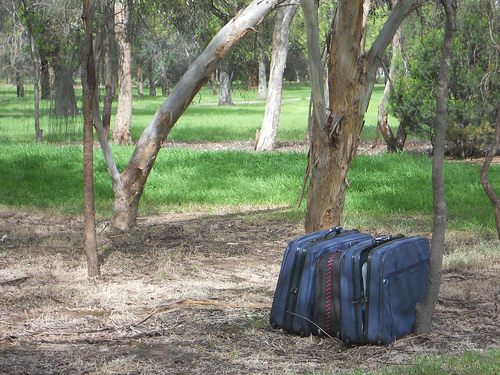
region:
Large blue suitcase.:
[341, 236, 430, 345]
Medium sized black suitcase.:
[307, 247, 348, 334]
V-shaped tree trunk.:
[379, 69, 406, 150]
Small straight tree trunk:
[80, 1, 95, 278]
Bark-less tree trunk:
[301, 0, 366, 230]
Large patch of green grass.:
[1, 155, 496, 205]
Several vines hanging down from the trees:
[45, 1, 80, 141]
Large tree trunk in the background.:
[252, 1, 301, 151]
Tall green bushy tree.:
[385, 0, 496, 155]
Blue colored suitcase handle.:
[320, 225, 342, 237]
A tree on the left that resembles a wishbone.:
[76, 0, 294, 232]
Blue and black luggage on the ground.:
[269, 226, 431, 351]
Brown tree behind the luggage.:
[301, 1, 426, 238]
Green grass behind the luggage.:
[1, 138, 499, 237]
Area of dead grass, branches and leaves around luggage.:
[0, 201, 499, 371]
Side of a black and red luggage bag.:
[313, 251, 341, 337]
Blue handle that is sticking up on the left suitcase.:
[322, 225, 342, 237]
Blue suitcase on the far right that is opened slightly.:
[333, 235, 433, 350]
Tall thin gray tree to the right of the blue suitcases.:
[409, 0, 459, 341]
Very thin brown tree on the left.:
[81, 0, 104, 280]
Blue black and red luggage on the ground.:
[268, 228, 434, 346]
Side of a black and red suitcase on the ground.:
[309, 250, 346, 337]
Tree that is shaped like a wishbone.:
[78, 0, 280, 236]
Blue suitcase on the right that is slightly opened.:
[338, 231, 433, 348]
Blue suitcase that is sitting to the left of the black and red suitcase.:
[268, 226, 372, 340]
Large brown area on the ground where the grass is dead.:
[1, 202, 498, 371]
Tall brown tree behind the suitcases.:
[297, 0, 429, 233]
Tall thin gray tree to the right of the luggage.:
[411, 0, 461, 337]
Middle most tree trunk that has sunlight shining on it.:
[254, 0, 297, 150]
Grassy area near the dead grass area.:
[1, 138, 498, 238]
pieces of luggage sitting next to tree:
[267, 211, 446, 356]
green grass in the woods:
[168, 148, 296, 217]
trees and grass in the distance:
[15, 7, 495, 187]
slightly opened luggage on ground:
[336, 231, 446, 346]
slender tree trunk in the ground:
[79, 77, 99, 282]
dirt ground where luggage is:
[113, 233, 276, 291]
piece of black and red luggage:
[312, 256, 346, 346]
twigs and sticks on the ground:
[26, 323, 191, 345]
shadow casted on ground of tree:
[147, 199, 299, 257]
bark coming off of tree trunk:
[319, 104, 358, 158]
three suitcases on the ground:
[263, 218, 435, 348]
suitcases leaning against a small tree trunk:
[267, 221, 447, 346]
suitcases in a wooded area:
[7, 9, 493, 366]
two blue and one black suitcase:
[266, 218, 431, 348]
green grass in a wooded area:
[4, 81, 499, 232]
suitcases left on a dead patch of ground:
[2, 206, 496, 374]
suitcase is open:
[340, 233, 431, 347]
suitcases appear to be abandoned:
[261, 226, 431, 348]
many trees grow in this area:
[3, 3, 498, 337]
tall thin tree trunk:
[77, 3, 107, 281]